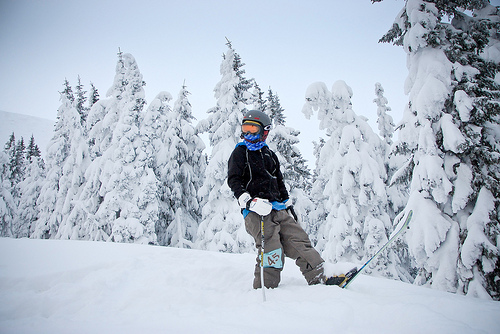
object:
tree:
[369, 2, 499, 301]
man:
[225, 111, 350, 290]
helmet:
[238, 106, 271, 143]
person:
[224, 109, 361, 288]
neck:
[236, 136, 272, 147]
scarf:
[232, 128, 270, 151]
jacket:
[223, 138, 341, 281]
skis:
[322, 210, 424, 286]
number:
[266, 251, 281, 266]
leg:
[244, 209, 284, 289]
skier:
[226, 109, 346, 288]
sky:
[4, 1, 423, 156]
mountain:
[0, 105, 68, 152]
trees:
[3, 2, 498, 291]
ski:
[330, 208, 411, 290]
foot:
[311, 268, 348, 288]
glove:
[238, 190, 276, 216]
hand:
[243, 197, 276, 218]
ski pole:
[256, 205, 267, 292]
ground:
[1, 231, 497, 330]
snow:
[3, 11, 497, 325]